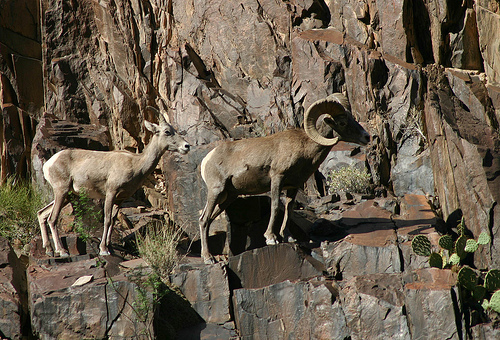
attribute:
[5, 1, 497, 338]
landscape — used by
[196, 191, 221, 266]
leg — gray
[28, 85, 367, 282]
goats — mountain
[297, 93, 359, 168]
horns — on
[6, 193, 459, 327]
ground — rocky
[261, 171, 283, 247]
leg — gray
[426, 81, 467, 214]
crack — on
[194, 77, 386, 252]
sheep — big horn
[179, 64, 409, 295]
goat — young, mountain goat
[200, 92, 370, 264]
sheep — big, horn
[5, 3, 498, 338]
hillface — rocky, large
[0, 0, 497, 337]
cliff — rocky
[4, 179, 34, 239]
bushes — on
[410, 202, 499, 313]
cacti — small, green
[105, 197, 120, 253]
leg — four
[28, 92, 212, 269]
ram — young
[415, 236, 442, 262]
cacti — green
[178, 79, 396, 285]
goat — large, horned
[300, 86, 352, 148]
curved horn — large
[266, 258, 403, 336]
rocks — sheer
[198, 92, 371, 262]
goat — male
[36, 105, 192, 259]
goat — younger, female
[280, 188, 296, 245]
leg — gray